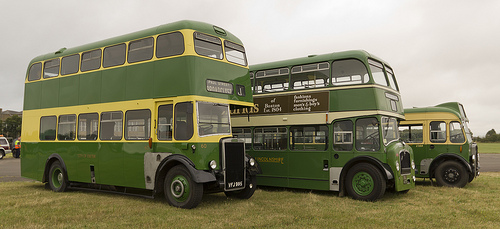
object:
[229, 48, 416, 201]
bus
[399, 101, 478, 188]
bus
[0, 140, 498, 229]
field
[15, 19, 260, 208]
bus